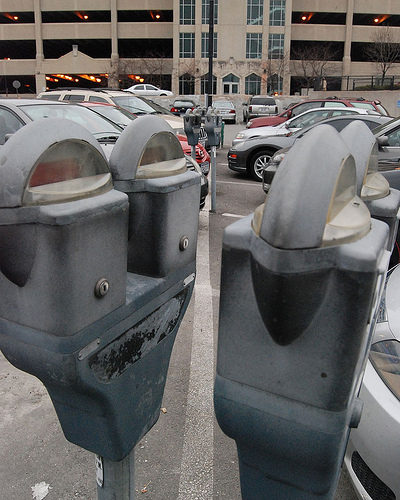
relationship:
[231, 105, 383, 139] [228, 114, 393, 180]
car next to car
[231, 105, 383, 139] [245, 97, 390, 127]
car next to car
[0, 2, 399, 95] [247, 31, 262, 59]
building with window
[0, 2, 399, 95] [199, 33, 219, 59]
building with window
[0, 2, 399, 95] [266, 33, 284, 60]
building with window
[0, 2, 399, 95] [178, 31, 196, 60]
building with window